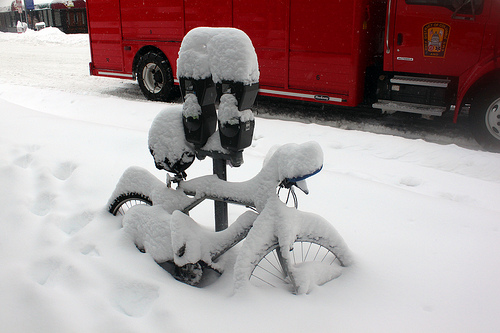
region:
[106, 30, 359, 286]
snow-covered bicycle leaning against a parking meter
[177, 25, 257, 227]
a black parking meter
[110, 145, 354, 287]
a bicyxle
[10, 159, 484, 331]
the sidewalk covered in snow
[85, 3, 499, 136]
a red fire engine in the road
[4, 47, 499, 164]
the road covered in snow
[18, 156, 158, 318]
footprints in snow beside the bike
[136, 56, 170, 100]
rear wheel of fire truck with chains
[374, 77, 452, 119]
silver colored metal steps to truck cab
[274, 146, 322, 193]
the bicycle handle bars covered in snow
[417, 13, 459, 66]
Emblem on the fire truck.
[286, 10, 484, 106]
Red truck parked on the street.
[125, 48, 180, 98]
Chains on the tire for better traction.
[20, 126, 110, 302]
Foot prints left by someone walking in the snow.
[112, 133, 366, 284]
Snow covered bike leaning against a meter.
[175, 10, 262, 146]
Snow covered parking meter.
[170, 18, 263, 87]
Six inches of snow has fallen.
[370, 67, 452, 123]
Silver steps leading into the truck.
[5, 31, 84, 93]
Tire track in the snow.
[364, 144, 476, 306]
Snow covering the street and sidewalk.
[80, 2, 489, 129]
a bright red city truck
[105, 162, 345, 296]
a bike buried in the snow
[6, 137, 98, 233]
footprints in the snow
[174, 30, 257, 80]
snow covering a parking meter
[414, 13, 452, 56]
a city logo on the truck door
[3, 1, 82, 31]
store fronts buildings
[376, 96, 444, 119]
a metal step on a truck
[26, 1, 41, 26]
a blue traffic sign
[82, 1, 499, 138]
A red firetruck in the snow.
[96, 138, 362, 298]
A bicycle covered in snow.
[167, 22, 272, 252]
A parking meter covered in snow.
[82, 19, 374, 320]
A bicycle and parking meter covered in snow.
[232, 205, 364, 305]
Only half of the bicycle wheel was visible in the snow.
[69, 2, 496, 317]
A firetruck is parked near a bicycle.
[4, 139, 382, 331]
Tracks in the snow near a bicycle.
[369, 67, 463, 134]
The steps of a firetruck.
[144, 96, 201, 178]
A bicycle helmet covered with snow.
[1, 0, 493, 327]
A bicycle waits for warmer days.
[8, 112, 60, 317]
The snow is the color white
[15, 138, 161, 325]
Tracks is the snow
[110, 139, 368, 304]
A bike in the snow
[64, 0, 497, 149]
A red truck parked on the street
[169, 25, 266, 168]
The parking pole on the sidewalk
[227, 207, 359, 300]
The front tire of the bike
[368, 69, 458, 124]
The steps on the truck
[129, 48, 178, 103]
The back tire of the truck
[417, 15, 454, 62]
The logo on the truck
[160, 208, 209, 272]
The pedal on the bike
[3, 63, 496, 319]
snow on the ground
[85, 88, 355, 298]
bike in the snow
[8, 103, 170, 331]
tracks in the snow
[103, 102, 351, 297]
snow on the bike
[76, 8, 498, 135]
truck on the road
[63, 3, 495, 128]
the truck is red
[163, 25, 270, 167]
snow on the parking meter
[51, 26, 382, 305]
bike next to car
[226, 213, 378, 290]
front tire of the bike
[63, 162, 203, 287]
back tire of bike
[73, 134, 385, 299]
bike covered in snow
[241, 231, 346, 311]
spokes on the bike